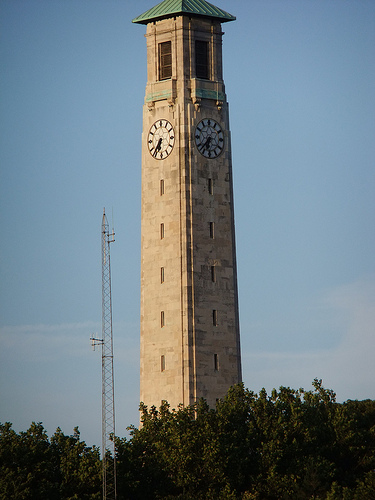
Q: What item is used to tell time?
A: A clock.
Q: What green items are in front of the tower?
A: A tree.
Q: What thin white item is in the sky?
A: A cloud.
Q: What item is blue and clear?
A: The sky.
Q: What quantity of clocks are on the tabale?
A: Two.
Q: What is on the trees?
A: Green leaves.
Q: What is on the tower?
A: A couple of clocks.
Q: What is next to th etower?
A: A metal tower.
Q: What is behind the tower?
A: A group of trees.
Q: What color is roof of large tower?
A: Green.